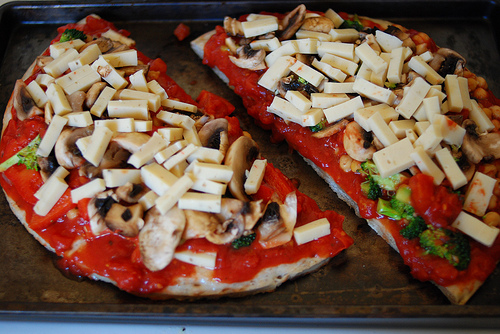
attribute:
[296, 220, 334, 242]
cheese — chunks, mozzarella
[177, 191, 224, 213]
cheese — rectangular, mozzarella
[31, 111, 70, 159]
cheese — white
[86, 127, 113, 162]
cheese — chunks, white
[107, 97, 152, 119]
cheese — rectangular, chunks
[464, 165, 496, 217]
cheese — white, mozzarella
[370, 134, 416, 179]
cheese — rectangular, mozzarella, chunks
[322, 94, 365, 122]
cheese — white, rectangular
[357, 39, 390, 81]
cheese — white, rectangular, mozzarella, chunks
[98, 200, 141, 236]
mushroom — brown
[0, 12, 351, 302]
pizza — uncooked, round, half, halved, raw, left half, here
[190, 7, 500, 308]
pizza — uncooked, round, half, halved, raw, right half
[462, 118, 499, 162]
mushroom — sliced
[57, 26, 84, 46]
broccoli — fresh, green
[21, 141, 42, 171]
broccoli — fresh, green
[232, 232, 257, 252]
broccoli — fresh, green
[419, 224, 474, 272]
broccoli — fresh, green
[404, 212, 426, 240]
broccoli — fresh, green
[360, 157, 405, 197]
broccoli — fresh, green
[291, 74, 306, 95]
broccoli — fresh, green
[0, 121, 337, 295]
sauce — red, tomato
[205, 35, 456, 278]
sauce — red, tomato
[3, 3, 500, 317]
pan — for baking, brown, metal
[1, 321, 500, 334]
surface — blue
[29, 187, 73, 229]
tomato — sliced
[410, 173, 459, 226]
tomato — sliced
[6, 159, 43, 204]
tomato — sliced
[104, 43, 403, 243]
space — empty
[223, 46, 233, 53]
broccoli — tiny, green, fresh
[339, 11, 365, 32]
broccoli — fresh, green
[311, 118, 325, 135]
broccoli — fresh, green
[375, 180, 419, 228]
broccoli — fresh, green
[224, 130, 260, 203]
mushroom — sliced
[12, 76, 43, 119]
mushroom — brown, sliced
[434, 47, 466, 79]
mushroom — brown, sliced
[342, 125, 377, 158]
mushroom — brown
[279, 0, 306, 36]
mushroom — brown, sliced